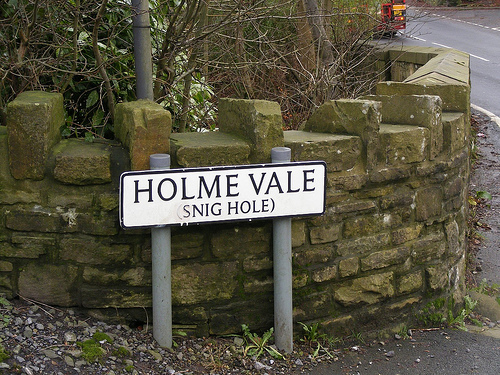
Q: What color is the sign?
A: White.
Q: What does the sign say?
A: Holme vale (snig hole).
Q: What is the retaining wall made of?
A: Stones.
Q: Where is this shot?
A: Sidewalk.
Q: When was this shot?
A: Daytime.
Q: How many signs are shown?
A: 1.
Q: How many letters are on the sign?
A: 17.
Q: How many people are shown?
A: 0.